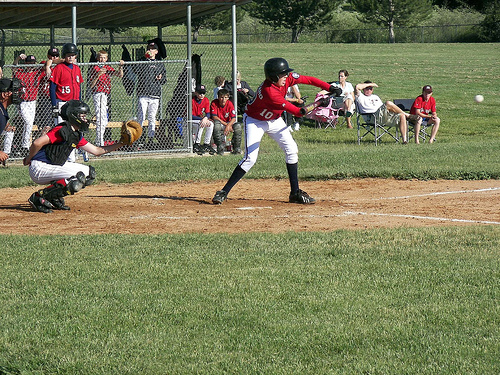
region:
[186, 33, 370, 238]
he is at bat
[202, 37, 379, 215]
he is preparing to bunt the ball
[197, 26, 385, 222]
he is going to bunt the ball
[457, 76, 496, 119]
this is a white baseball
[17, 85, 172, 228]
he is a catcher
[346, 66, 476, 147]
these people are watching the game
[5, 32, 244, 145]
this is the dugout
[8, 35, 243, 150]
players in the dugout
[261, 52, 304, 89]
a black batting helmet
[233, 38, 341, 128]
his jersey number is 10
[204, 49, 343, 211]
boy is holding a bat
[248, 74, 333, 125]
boy's shirt is red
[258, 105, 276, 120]
white numbers on shirt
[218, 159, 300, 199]
boy's socks are black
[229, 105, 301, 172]
boy's pants are white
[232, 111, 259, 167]
black stripe on boy's pants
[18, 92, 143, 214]
man is squatting down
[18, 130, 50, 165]
man's arm behind back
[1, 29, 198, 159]
players standing behind metal fence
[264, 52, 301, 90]
player wearing a hat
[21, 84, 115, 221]
Catcher is squatting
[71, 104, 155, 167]
Catcher is holding glove out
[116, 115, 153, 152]
This is a catcher's mitt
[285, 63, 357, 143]
Player is swinging bat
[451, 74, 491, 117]
Ball is flying through air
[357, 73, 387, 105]
Man is covering face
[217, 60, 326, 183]
The uniform is red and white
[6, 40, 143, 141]
Players are standing in background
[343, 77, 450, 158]
People are sitting down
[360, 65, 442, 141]
People are watching game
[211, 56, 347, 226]
boy in red shirt swinging baseball bat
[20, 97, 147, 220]
catcher squating behind hitter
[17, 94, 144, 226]
catcher holding baseball glove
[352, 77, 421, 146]
man in white shirt sitting in chair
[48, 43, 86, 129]
boy in red shirt standing in front of fence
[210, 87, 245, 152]
boy in red shirt watching baseball game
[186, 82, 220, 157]
boy in red shirt sitting beside of fence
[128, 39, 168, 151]
boy in blue shirt taking a drink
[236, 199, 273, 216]
white base at home plate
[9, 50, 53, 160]
boy in red shirt leaning against fence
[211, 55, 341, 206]
A kid in red and white.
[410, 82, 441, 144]
A person in a red shirt.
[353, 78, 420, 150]
A man sitting down.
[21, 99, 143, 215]
A baseball catcher squatting.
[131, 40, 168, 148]
A person in black jacket.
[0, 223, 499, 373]
A green baseball field.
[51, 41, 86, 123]
A kid wearing a helmet.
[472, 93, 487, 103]
A round white ball.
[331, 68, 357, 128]
A woman sitting down.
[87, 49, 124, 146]
A kid in red and white.